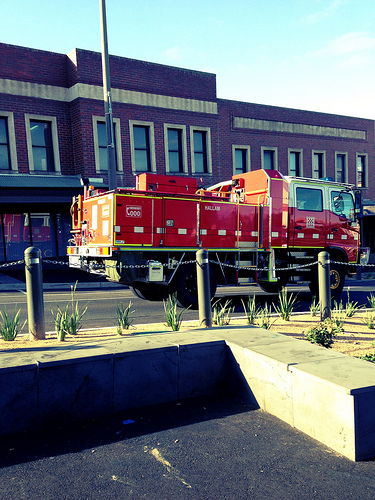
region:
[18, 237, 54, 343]
pole of a fence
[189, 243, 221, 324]
pole of a fence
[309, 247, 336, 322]
pole of a fence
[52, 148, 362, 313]
truck of fire fighters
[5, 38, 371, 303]
a truck in front a building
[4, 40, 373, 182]
red building of brick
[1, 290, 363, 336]
green plants near the fence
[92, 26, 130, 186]
a pole in front a building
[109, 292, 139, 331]
a green plant growing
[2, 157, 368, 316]
a large red truck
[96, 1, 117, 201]
a tall wooden pole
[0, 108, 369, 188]
a row of windows on a building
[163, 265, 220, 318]
back tire on a truck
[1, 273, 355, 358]
the sun shinning on the ground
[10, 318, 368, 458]
a concrete wall here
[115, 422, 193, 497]
some yellow paint on ground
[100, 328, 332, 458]
a shadow on the wall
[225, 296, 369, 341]
shadows of the poles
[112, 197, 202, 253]
red compartments on back of truck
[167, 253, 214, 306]
black tires on truck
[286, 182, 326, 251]
door on side of truck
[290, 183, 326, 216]
window on side of truck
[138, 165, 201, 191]
red container on top of truck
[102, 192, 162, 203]
yellow boarder on side of truck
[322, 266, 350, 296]
black front wheel of truck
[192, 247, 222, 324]
metal post in the ground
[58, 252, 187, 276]
silver chain of fence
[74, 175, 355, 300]
a large red truck in the street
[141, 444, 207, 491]
tan markings on the cement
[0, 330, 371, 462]
a concrete ledge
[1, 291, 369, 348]
little plants in the dirt by the road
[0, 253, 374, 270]
a chain connecting the metal poles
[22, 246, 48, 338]
a metal pole by the sidewalk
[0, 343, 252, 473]
a shadow cast by the ledge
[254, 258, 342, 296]
the front wheels of the truck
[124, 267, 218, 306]
the back wheels of the truck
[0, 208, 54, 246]
the reflection of the truck in a window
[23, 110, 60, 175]
a window of a building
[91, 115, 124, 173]
a window of a building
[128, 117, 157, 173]
a window of a building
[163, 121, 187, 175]
a window of a building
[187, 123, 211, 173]
a window of a building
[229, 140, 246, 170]
a window of a building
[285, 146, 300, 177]
a window of a building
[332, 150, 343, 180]
a window of a building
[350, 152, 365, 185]
a window of a building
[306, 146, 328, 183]
a window of a building